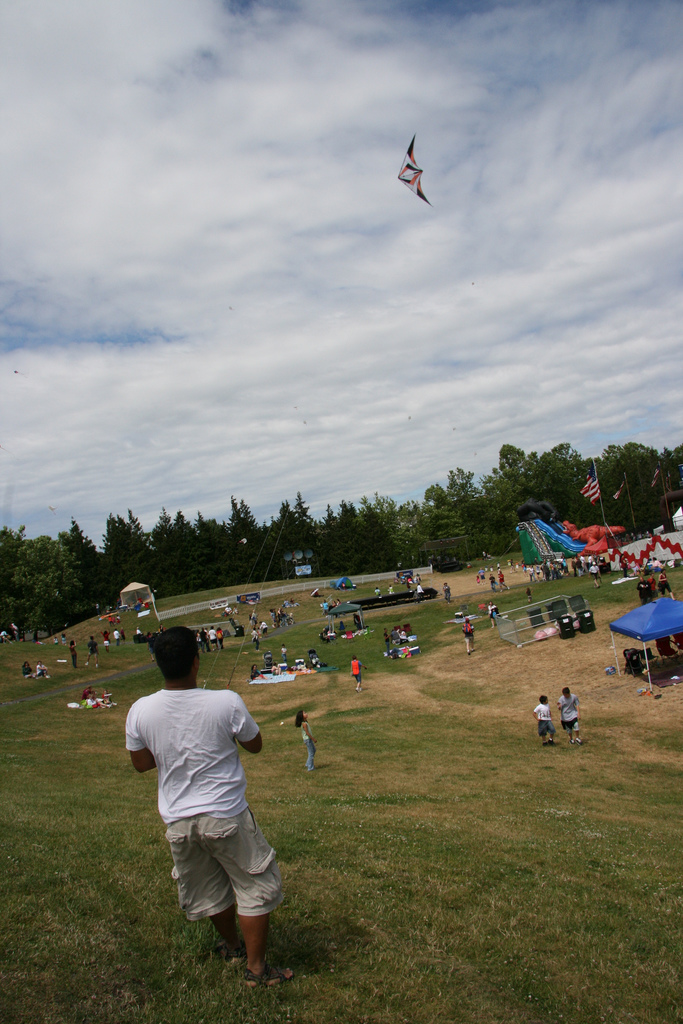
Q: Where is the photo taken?
A: At a park.